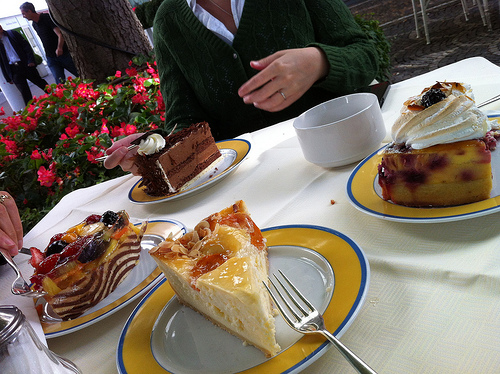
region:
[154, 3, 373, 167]
person wearing green shirt eating cake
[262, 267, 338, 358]
silver fork on white yellow and blue plate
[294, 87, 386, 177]
white coffee cup on table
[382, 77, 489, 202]
whipped topping on fruit cake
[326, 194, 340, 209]
pierce of strawberry on tablecloth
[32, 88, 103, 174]
red flowers beside of table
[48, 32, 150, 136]
red flower around tree trunk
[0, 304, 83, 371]
silver and glass sugar container by desert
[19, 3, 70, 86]
man in black talking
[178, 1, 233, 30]
silver necklace on neck of woman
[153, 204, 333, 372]
a piece of cheesecake on a yellow and white plate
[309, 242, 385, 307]
blue and yellow trim of the plate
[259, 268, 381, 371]
a grey metal fork set on a plate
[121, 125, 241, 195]
a piece of chocolate cake on a yellow and white plate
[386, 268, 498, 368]
white fabric patterned table cloth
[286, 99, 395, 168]
a white porcelain bowl on the table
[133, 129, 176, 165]
white icing on top of the chocolate cake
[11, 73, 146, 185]
flowers growing next to the table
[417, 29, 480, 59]
grey stones of the ground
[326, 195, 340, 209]
a single crumb on the tablecloth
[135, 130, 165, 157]
Whip cream on a slice of cake.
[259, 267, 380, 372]
A fork in a plate.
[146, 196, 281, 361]
A delicious piece of pie.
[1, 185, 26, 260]
A person's hand holding a fork.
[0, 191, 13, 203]
A ring on a person's hand.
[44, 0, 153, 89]
The trunk of a tree.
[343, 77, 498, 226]
A plate of dessert.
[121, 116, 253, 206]
A piece of cake on a plate.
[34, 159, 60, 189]
A flower on a bush.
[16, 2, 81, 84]
A man wearing a black shirt.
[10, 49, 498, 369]
table with three plates of food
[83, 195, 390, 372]
plate is yellow and white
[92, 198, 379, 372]
plate has blue trim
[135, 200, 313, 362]
pie is off white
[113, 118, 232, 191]
pie is dark brown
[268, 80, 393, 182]
white cup on table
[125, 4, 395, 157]
person wearing green sweater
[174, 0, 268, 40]
person wearing white shirt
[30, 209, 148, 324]
fruit on top of pie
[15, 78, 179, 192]
bush has red flowers